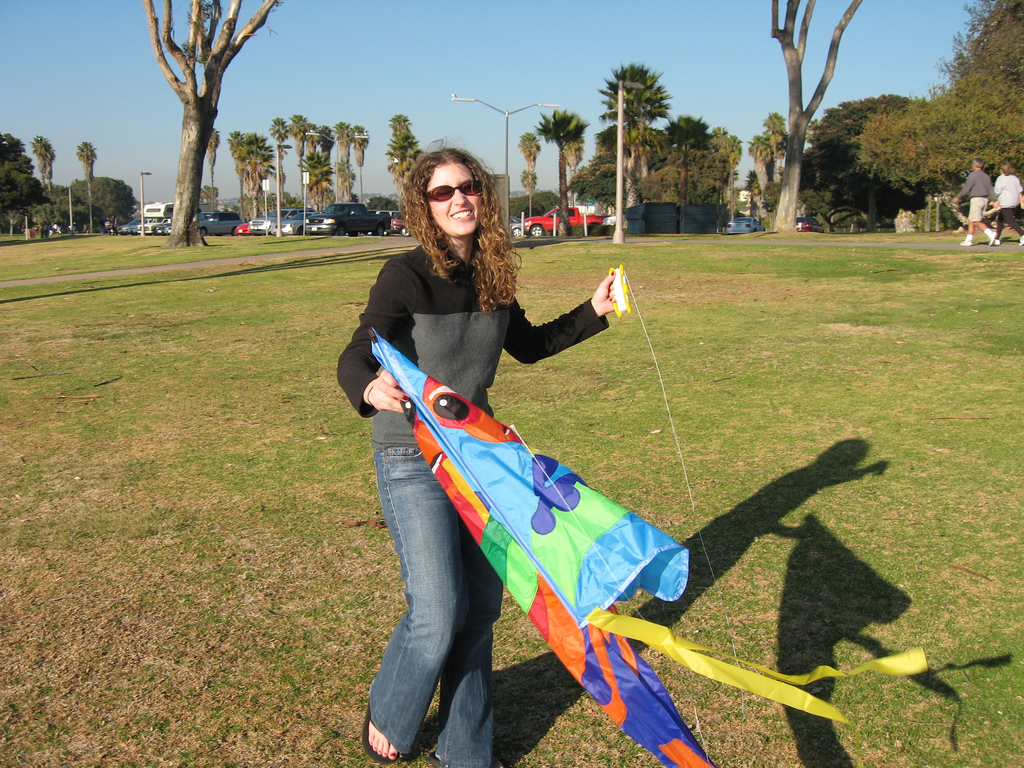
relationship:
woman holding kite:
[345, 141, 529, 764] [359, 326, 931, 768]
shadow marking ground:
[438, 438, 1008, 768] [520, 389, 989, 748]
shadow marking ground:
[777, 510, 1012, 766] [520, 389, 989, 748]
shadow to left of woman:
[438, 440, 890, 766] [336, 150, 629, 768]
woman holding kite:
[336, 150, 629, 768] [358, 335, 847, 753]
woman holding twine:
[336, 150, 629, 768] [591, 245, 687, 436]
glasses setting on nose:
[424, 178, 481, 202] [455, 188, 466, 204]